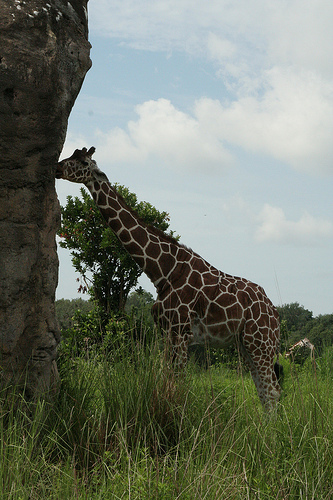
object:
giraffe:
[55, 146, 283, 420]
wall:
[1, 0, 93, 421]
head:
[53, 146, 109, 184]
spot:
[144, 238, 157, 252]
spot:
[116, 216, 132, 230]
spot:
[188, 260, 206, 273]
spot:
[213, 292, 228, 312]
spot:
[174, 284, 192, 306]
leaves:
[56, 184, 181, 265]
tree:
[57, 182, 181, 360]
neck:
[84, 177, 179, 293]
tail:
[274, 306, 285, 385]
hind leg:
[241, 306, 283, 414]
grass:
[1, 326, 332, 499]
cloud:
[248, 200, 332, 248]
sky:
[135, 1, 332, 125]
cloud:
[244, 44, 322, 97]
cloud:
[127, 104, 195, 162]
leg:
[158, 299, 194, 381]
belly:
[184, 303, 247, 349]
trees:
[279, 301, 333, 356]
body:
[150, 244, 279, 351]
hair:
[274, 362, 284, 385]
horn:
[87, 146, 96, 156]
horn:
[82, 146, 87, 152]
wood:
[285, 337, 316, 360]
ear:
[90, 168, 109, 182]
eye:
[81, 159, 89, 167]